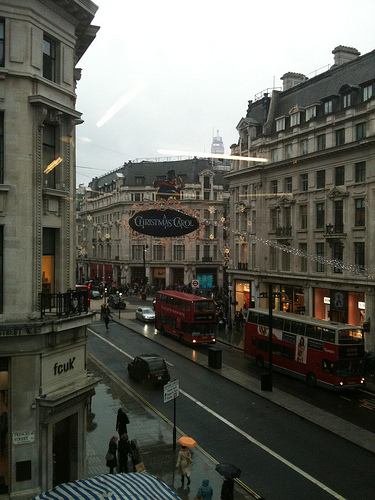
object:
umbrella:
[177, 434, 198, 450]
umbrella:
[214, 461, 244, 480]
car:
[124, 349, 172, 391]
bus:
[154, 288, 218, 351]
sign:
[128, 206, 200, 237]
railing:
[38, 287, 90, 320]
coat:
[176, 446, 195, 479]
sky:
[78, 1, 375, 180]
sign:
[163, 378, 181, 401]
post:
[171, 399, 177, 453]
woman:
[175, 444, 195, 491]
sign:
[52, 352, 78, 378]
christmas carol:
[133, 213, 195, 232]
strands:
[198, 216, 375, 279]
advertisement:
[294, 334, 308, 366]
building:
[75, 155, 228, 290]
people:
[99, 308, 113, 334]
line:
[88, 328, 345, 500]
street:
[80, 290, 375, 499]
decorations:
[124, 198, 206, 245]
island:
[85, 293, 374, 500]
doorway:
[48, 408, 84, 486]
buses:
[240, 300, 369, 398]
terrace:
[36, 277, 97, 333]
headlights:
[144, 316, 149, 320]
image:
[153, 167, 186, 201]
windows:
[351, 158, 369, 185]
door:
[52, 428, 71, 484]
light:
[118, 290, 122, 319]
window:
[148, 358, 165, 371]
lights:
[155, 143, 268, 166]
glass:
[1, 1, 374, 499]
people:
[112, 400, 132, 443]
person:
[217, 467, 239, 500]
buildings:
[0, 1, 103, 500]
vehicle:
[135, 305, 156, 325]